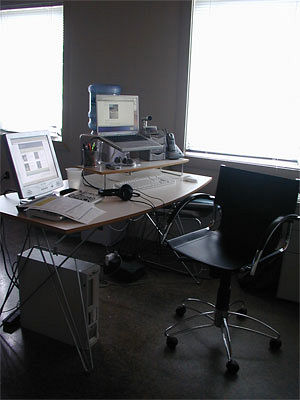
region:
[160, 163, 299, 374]
A black and metal desk chair.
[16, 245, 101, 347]
A long thin white cpu unit on the floor.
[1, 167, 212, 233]
The wooden long desk top.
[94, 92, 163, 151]
A grey laptop up higher.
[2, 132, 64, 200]
A tilted back silver monitor.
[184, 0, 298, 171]
A large lit up window behind the black chair.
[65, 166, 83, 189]
A clear plastic cup of water in front of a monitor.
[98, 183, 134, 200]
Black headphones on a desk.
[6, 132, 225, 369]
A silver framed desk with a wooden desktop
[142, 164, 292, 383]
A black desk chair on wheels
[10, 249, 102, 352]
A beige computer processing unit on the floor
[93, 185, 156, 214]
A black pair of headphones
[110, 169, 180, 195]
A white keyboard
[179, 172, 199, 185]
A computer mouse on the desk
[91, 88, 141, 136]
A silver laptop with a black keyboard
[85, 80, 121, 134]
A blue bottle of water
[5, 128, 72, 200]
A computer monitor turned on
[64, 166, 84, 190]
A clear plastic cup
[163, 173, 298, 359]
this is a chair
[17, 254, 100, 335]
this is a CPU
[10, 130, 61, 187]
THIS IS A MONITOR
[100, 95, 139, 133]
THIS IS A MONITOR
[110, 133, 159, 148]
THIS IS A keyboard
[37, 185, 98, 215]
THIS IS A keyboard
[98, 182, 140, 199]
this are head phones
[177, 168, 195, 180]
this is a mouse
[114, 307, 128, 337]
this is the floor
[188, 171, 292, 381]
this is a chair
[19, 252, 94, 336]
this is a C P U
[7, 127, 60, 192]
THIS IS A MONITOR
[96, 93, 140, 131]
THIS IS A MONITOR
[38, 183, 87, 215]
THIS IS A KEY BOARD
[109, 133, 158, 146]
THIS IS A KEY BOARD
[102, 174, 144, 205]
THESE ARE HEAD PHONES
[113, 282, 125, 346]
THIS IS THE FLOOR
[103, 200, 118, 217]
THIS IS THE TABLE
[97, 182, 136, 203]
Headphones on a desk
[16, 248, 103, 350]
Computer tower under a desk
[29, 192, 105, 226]
Papers on a keyboard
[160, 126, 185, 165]
Phone by a computer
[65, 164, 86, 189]
Clear cup on desk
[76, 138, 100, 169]
A cup full of pens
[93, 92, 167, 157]
Laptop on a desk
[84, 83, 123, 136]
Water dispenser behind a desk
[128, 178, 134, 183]
a key on a keyboard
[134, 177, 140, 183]
a key on a keyboard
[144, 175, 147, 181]
a key on a keyboard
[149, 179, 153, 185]
a key on a keyboard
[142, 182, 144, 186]
a key on a keyboard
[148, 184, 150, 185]
a key on a keyboard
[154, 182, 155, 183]
a key on a keyboard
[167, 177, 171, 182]
a key on a keyboard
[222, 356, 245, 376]
black plastic wheel of a chair